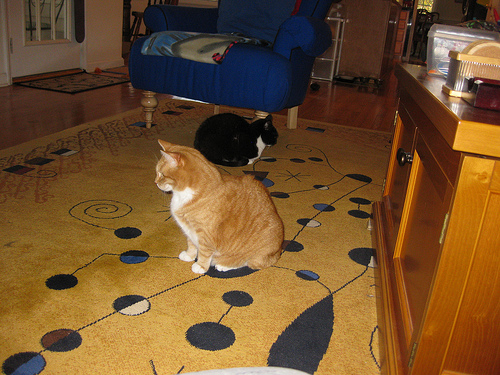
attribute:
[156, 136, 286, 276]
cat — orange, white, brown, yellow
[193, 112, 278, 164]
cat — black, white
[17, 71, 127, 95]
mat — for feet wiping, colorful, welcome mat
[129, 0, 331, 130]
chair — blue, deep blue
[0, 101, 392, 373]
carpet — circled, linen, patterned, large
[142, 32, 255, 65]
blanket — blue, red, tan, folded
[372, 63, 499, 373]
cabinet — wooden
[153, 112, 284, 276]
cats — opposites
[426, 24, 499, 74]
container — plastic, white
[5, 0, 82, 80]
door — white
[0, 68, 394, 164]
floor — wooden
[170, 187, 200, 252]
fur — white